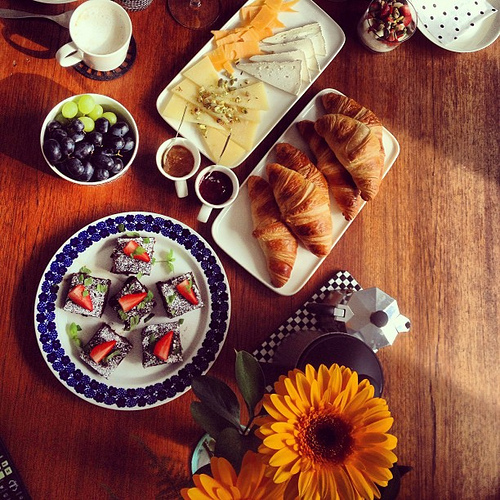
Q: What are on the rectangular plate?
A: Croissants.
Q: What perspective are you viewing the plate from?
A: Birds-eye view.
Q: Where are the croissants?
A: On the rectangular plate.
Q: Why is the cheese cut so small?
A: To fit on a cracker.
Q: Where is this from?
A: The garden.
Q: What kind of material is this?
A: Wood.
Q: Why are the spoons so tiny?
A: To serve sauces.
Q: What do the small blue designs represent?
A: Flowers.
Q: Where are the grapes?
A: In the round bowl.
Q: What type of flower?
A: Sunflower.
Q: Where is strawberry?
A: On brownie.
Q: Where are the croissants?
A: On plate.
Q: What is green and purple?
A: Grapes.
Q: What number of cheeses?
A: Three.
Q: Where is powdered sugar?
A: On brownies.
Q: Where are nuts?
A: In cheese.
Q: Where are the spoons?
A: In ramekin.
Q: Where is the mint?
A: On brownies.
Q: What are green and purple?
A: Grapes.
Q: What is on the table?
A: Stuff.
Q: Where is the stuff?
A: On the table.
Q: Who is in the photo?
A: No people.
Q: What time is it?
A: Afternoon.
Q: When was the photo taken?
A: During the daytime.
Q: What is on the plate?
A: Food.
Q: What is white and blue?
A: The plate.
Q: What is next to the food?
A: A cup.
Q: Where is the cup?
A: On the brown table.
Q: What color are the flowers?
A: Yellow.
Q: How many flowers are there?
A: Two.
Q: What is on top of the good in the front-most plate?
A: Strawberries.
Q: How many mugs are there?
A: One.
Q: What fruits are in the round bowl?
A: Grapes and blueberries.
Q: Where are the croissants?
A: On a plate.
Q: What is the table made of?
A: Wood.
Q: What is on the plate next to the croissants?
A: Cheese.